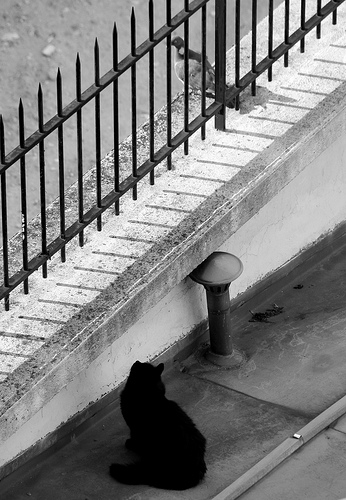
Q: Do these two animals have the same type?
A: No, they are birds and cats.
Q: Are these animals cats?
A: No, they are birds and cats.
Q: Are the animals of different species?
A: Yes, they are birds and cats.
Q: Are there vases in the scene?
A: No, there are no vases.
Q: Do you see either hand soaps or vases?
A: No, there are no vases or hand soaps.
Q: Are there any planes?
A: No, there are no planes.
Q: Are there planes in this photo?
A: No, there are no planes.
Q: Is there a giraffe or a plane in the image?
A: No, there are no airplanes or giraffes.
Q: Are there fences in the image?
A: Yes, there is a fence.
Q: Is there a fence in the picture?
A: Yes, there is a fence.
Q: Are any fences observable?
A: Yes, there is a fence.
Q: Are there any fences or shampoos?
A: Yes, there is a fence.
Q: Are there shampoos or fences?
A: Yes, there is a fence.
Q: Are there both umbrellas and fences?
A: No, there is a fence but no umbrellas.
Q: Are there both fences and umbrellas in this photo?
A: No, there is a fence but no umbrellas.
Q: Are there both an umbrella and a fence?
A: No, there is a fence but no umbrellas.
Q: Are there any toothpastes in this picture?
A: No, there are no toothpastes.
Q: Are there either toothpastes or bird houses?
A: No, there are no toothpastes or bird houses.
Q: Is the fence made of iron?
A: Yes, the fence is made of iron.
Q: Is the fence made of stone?
A: No, the fence is made of iron.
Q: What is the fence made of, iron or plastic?
A: The fence is made of iron.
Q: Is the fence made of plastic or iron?
A: The fence is made of iron.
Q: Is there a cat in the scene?
A: Yes, there is a cat.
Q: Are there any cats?
A: Yes, there is a cat.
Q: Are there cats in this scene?
A: Yes, there is a cat.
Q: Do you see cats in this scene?
A: Yes, there is a cat.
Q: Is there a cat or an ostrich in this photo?
A: Yes, there is a cat.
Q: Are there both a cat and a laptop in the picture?
A: No, there is a cat but no laptops.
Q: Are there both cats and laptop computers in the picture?
A: No, there is a cat but no laptops.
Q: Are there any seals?
A: No, there are no seals.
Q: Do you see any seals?
A: No, there are no seals.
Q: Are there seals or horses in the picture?
A: No, there are no seals or horses.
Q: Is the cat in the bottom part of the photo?
A: Yes, the cat is in the bottom of the image.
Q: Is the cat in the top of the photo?
A: No, the cat is in the bottom of the image.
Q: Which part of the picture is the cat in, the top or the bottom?
A: The cat is in the bottom of the image.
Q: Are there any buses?
A: No, there are no buses.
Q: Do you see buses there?
A: No, there are no buses.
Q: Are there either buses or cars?
A: No, there are no buses or cars.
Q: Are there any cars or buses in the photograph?
A: No, there are no buses or cars.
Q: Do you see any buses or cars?
A: No, there are no buses or cars.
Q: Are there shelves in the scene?
A: No, there are no shelves.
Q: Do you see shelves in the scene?
A: No, there are no shelves.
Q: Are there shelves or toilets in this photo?
A: No, there are no shelves or toilets.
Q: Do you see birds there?
A: Yes, there is a bird.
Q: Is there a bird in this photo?
A: Yes, there is a bird.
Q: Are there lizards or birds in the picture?
A: Yes, there is a bird.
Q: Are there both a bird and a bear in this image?
A: No, there is a bird but no bears.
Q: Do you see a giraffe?
A: No, there are no giraffes.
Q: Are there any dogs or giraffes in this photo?
A: No, there are no giraffes or dogs.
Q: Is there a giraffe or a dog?
A: No, there are no giraffes or dogs.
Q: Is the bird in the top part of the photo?
A: Yes, the bird is in the top of the image.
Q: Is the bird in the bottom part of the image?
A: No, the bird is in the top of the image.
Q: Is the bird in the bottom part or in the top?
A: The bird is in the top of the image.